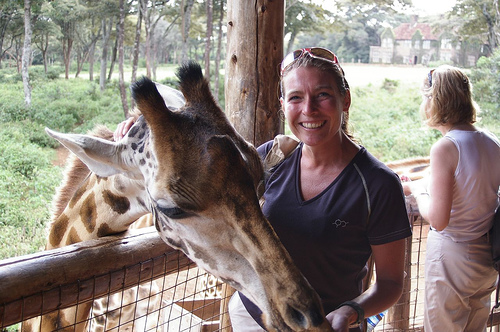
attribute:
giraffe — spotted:
[13, 60, 341, 331]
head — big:
[120, 61, 332, 331]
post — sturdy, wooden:
[221, 1, 287, 146]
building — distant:
[365, 15, 476, 70]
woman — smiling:
[226, 46, 412, 331]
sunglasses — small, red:
[272, 46, 347, 92]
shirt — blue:
[240, 139, 416, 331]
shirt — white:
[434, 125, 500, 244]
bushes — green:
[2, 65, 133, 256]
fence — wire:
[2, 184, 496, 330]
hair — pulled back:
[270, 43, 351, 97]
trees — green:
[0, 1, 412, 121]